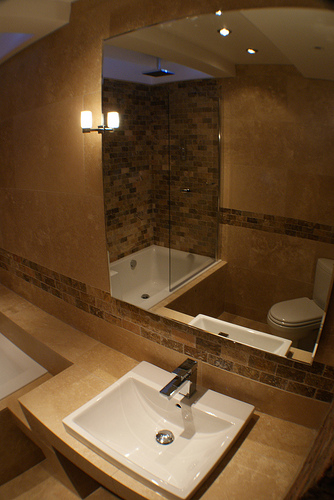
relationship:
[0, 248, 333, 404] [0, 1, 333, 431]
backsplash on wall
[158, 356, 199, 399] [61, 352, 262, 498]
faucet on sink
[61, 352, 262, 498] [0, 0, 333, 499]
sink in bathroom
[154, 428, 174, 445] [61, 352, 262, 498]
drain in sink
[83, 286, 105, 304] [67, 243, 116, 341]
tile on wall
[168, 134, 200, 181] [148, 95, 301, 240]
tile in wall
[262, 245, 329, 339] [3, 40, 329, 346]
toilet in bathroom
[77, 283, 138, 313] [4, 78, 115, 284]
tile in wall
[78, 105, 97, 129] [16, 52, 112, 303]
light on wall